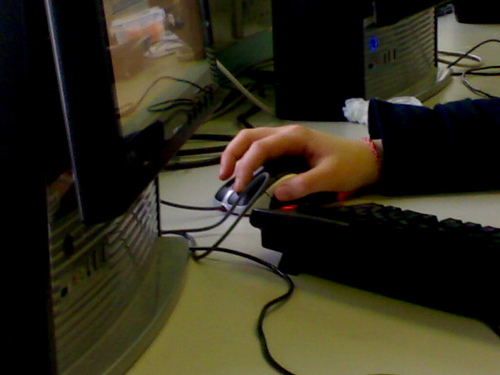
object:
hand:
[217, 121, 383, 201]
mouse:
[215, 151, 352, 217]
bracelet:
[364, 131, 386, 174]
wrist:
[343, 121, 386, 194]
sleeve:
[366, 95, 499, 198]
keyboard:
[250, 199, 499, 325]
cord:
[255, 253, 300, 374]